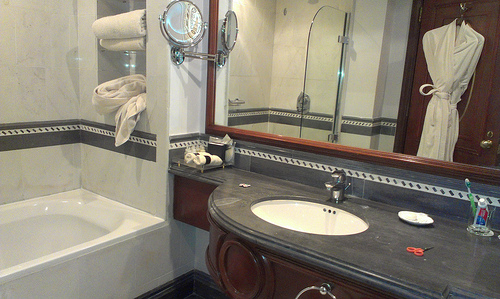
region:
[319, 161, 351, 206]
a faucet above a sink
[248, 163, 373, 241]
the sink is white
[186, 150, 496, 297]
the counter is black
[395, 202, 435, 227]
a white dish soap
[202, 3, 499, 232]
a mirror in front a sink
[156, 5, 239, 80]
a mirror color silver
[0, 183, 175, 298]
a white tub with water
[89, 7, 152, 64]
the towel is white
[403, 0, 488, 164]
a white robe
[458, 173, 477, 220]
the toothbrush is green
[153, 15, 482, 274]
view is in a bathroom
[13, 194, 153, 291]
bathtub is white in color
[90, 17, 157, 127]
towela are on hanger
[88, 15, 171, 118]
towels are white in color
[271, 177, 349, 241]
sink is white in color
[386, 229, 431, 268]
scisors are maroon in color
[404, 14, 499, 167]
bathing robe is on hanger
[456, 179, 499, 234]
tooth paste and brush are in a glass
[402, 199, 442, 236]
soa[ dish is white in color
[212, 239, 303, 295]
drawers are wooden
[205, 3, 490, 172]
mirror above the sink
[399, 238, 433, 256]
scissors on the countertop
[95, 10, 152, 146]
towels stacked above bathtub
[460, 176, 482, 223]
green handled toothbrush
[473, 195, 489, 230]
tube of toothpaste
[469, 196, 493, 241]
clear glass toothpaste and toothbrush is in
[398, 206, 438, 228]
white soap dish on the countetop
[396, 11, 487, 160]
white robe hanging on the door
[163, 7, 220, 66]
adjustable vanity mirror attached to large mirror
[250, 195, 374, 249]
white sink in the countertop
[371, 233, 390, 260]
the counter is grey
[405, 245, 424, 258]
the handle is orange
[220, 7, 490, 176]
reflection is on the mirror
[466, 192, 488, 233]
toothpaste is in the glass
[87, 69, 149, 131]
the towels are white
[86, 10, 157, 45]
the towel is folded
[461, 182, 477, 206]
the toothbrush is blue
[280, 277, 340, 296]
the handle is silver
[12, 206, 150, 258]
the bathtub is clean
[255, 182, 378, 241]
the sink is oval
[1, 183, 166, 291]
white bathtub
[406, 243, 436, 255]
orange handled scissors on a counter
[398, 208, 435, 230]
soap dish on a counter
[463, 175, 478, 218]
green toothbrush in a glass cup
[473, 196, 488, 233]
tube of toothpaste in a glass cup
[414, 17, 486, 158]
white bathrobe hanging on a door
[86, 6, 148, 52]
two neatly folded white towels on a shelf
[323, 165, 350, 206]
water faucet on a sink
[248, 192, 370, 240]
white sink basin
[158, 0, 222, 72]
magnifying mirror on a wall